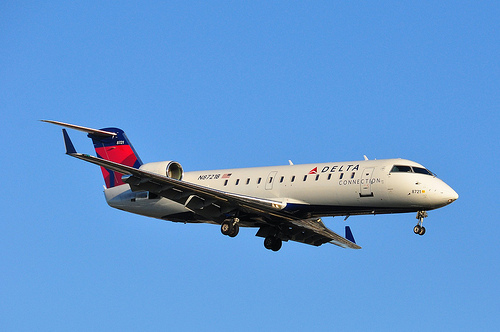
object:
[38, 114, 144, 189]
tail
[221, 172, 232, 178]
flag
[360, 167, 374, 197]
door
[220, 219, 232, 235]
wheel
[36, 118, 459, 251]
airplane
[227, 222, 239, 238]
wheels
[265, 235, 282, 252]
wheels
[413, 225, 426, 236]
wheels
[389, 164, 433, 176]
pilot windows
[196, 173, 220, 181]
number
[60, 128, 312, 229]
airplane wings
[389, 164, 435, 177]
window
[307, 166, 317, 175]
red symbol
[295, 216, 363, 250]
left wing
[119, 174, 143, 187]
light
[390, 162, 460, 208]
nose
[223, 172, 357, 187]
windows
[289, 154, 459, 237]
front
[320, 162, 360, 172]
delta name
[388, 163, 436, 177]
pilot's cockpit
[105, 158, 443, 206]
side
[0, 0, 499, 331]
sky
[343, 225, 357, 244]
tip